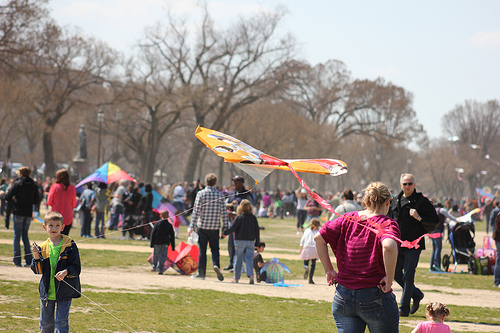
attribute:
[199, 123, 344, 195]
kite — held, multicolored, airborn, triangualar, colorful, flown, red, ellow, air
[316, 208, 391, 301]
shirt — pink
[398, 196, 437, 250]
jacket — black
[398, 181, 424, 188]
sunglasses — worn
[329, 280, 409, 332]
jeans — worn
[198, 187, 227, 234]
plaid — worn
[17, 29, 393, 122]
trees — background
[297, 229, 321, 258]
blouse — worn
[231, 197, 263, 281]
woman — walkig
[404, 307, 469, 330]
girl — small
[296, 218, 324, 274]
child — walking